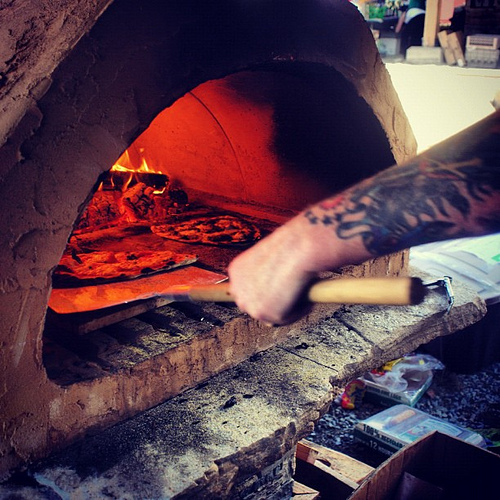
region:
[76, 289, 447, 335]
wooden paddle to get pizza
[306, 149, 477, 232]
tattoos on the arm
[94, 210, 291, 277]
pizza in the oven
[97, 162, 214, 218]
fire in the oven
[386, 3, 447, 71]
woman across the street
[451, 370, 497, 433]
gray gravel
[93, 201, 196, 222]
ashes in the oven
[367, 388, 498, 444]
containers in the gravel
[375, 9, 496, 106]
it is light out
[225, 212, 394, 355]
holding the shovel with left hand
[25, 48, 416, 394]
outdoor pizza oven is red inside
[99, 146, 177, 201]
flames deep in oven's pit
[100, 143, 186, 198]
flames are yellow+orange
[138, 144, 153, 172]
flame is pointy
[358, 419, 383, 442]
100% in blue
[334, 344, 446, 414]
a crumpled plastic covered packet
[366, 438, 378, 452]
12 in white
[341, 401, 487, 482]
a largely white packet; a largely black packet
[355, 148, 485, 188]
a tattoo w/ a crucifix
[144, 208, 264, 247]
a small wrinkly pizza shaded red by flames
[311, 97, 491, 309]
An arm full of tattoos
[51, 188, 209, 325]
Brick oven pizza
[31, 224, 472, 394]
A wood and silver pizza utinsel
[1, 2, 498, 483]
A big brick oven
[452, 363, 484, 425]
Gravel on the ground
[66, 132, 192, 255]
Open flame in the brick oven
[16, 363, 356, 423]
Ash and dirt from the oven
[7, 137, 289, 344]
Two different pizzas cooking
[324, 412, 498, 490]
A piece of the cardboard box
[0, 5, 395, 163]
A large brick fixture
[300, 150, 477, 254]
Tattoos on the left arm of a person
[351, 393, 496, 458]
Two books stacked on the ground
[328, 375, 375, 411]
Colorful plastic bag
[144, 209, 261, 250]
Pizza in a pizza oven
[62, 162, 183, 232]
Wood burning in a pizza oven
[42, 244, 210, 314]
Pizza under a wooden pizza server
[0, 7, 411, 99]
Ceramic top of a pizza oven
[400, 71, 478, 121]
Sun reflecting off the ground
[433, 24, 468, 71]
Two cardboard boxes leaning against a post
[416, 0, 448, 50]
Wooden post on a concrete base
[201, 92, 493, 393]
man with tattoo on arm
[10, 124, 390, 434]
man using pizza oven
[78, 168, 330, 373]
pizza in brick fired oven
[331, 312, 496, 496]
plastic boxes on ground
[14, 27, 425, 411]
brick fired pizza oven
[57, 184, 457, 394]
man holding giant pizza spatula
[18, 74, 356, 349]
two pizzas in brick fired oven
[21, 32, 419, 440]
pizza oven in photograph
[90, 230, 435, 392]
man holding spatula handle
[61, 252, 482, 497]
ash on outside of oven